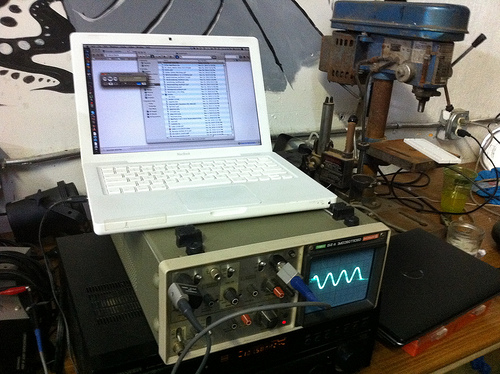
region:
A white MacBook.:
[60, 20, 357, 250]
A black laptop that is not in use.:
[375, 225, 495, 360]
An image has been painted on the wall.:
[5, 0, 325, 96]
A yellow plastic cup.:
[432, 155, 474, 212]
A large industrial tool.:
[317, 0, 469, 215]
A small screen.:
[300, 241, 375, 321]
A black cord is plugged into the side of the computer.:
[30, 165, 95, 370]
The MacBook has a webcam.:
[155, 21, 180, 46]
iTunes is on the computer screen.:
[131, 50, 237, 147]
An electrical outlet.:
[435, 100, 475, 147]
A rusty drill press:
[306, 0, 476, 182]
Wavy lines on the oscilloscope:
[302, 235, 381, 318]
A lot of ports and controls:
[151, 241, 311, 349]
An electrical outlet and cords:
[434, 98, 486, 154]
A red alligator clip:
[0, 270, 42, 312]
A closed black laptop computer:
[368, 215, 499, 357]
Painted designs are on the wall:
[2, 1, 70, 118]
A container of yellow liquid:
[424, 155, 493, 214]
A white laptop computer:
[50, 17, 358, 234]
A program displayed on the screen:
[83, 45, 257, 144]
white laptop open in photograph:
[64, 18, 331, 223]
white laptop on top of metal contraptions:
[27, 12, 404, 330]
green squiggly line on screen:
[311, 185, 393, 327]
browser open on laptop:
[98, 50, 255, 141]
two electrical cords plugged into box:
[164, 267, 332, 352]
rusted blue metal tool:
[338, 20, 455, 194]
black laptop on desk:
[381, 227, 476, 371]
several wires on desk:
[347, 134, 497, 221]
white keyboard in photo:
[88, 162, 280, 199]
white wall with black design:
[2, 11, 162, 133]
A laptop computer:
[38, 20, 333, 260]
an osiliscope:
[281, 226, 406, 322]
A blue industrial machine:
[304, 1, 489, 171]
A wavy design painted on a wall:
[4, 5, 65, 111]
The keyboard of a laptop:
[79, 142, 297, 205]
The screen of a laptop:
[83, 36, 259, 150]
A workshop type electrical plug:
[436, 94, 498, 153]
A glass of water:
[435, 202, 487, 273]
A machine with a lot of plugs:
[141, 245, 310, 357]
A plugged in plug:
[264, 252, 330, 316]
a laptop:
[63, 25, 346, 240]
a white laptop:
[65, 30, 348, 245]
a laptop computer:
[61, 30, 342, 237]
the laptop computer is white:
[68, 27, 338, 239]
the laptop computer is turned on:
[63, 25, 345, 237]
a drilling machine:
[322, 2, 482, 238]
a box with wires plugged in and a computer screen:
[135, 221, 398, 363]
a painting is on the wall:
[3, 2, 498, 154]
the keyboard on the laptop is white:
[68, 27, 354, 235]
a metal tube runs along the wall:
[6, 108, 497, 174]